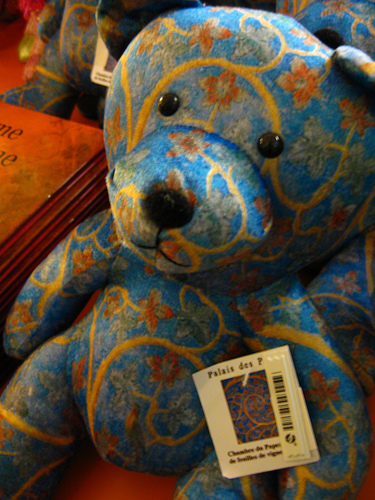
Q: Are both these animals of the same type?
A: No, they are birds and bears.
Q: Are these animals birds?
A: No, they are birds and bears.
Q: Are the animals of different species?
A: Yes, they are birds and bears.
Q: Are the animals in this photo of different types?
A: Yes, they are birds and bears.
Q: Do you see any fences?
A: No, there are no fences.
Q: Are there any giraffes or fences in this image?
A: No, there are no fences or giraffes.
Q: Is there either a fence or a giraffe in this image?
A: No, there are no fences or giraffes.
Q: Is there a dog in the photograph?
A: No, there are no dogs.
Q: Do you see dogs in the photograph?
A: No, there are no dogs.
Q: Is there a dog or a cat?
A: No, there are no dogs or cats.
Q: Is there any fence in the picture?
A: No, there are no fences.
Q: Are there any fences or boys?
A: No, there are no fences or boys.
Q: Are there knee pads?
A: No, there are no knee pads.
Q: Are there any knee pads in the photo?
A: No, there are no knee pads.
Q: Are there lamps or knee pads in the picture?
A: No, there are no knee pads or lamps.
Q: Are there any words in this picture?
A: Yes, there are words.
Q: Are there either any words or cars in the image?
A: Yes, there are words.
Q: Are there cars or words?
A: Yes, there are words.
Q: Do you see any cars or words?
A: Yes, there are words.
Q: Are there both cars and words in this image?
A: No, there are words but no cars.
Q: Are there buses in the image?
A: No, there are no buses.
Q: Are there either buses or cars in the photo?
A: No, there are no buses or cars.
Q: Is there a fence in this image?
A: No, there are no fences.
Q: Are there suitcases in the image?
A: No, there are no suitcases.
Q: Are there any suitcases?
A: No, there are no suitcases.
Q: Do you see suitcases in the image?
A: No, there are no suitcases.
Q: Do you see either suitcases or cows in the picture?
A: No, there are no suitcases or cows.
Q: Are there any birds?
A: Yes, there is a bird.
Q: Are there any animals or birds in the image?
A: Yes, there is a bird.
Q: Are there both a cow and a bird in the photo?
A: No, there is a bird but no cows.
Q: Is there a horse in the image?
A: No, there are no horses.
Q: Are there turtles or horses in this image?
A: No, there are no horses or turtles.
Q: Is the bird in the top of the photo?
A: Yes, the bird is in the top of the image.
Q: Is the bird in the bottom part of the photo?
A: No, the bird is in the top of the image.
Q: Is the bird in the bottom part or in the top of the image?
A: The bird is in the top of the image.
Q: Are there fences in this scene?
A: No, there are no fences.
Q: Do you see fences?
A: No, there are no fences.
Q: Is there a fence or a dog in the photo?
A: No, there are no fences or dogs.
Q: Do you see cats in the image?
A: No, there are no cats.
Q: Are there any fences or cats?
A: No, there are no cats or fences.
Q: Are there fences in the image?
A: No, there are no fences.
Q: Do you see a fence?
A: No, there are no fences.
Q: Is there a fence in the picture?
A: No, there are no fences.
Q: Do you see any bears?
A: Yes, there is a bear.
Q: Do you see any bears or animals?
A: Yes, there is a bear.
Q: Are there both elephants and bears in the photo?
A: No, there is a bear but no elephants.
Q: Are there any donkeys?
A: No, there are no donkeys.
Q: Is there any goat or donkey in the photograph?
A: No, there are no donkeys or goats.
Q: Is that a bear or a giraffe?
A: That is a bear.